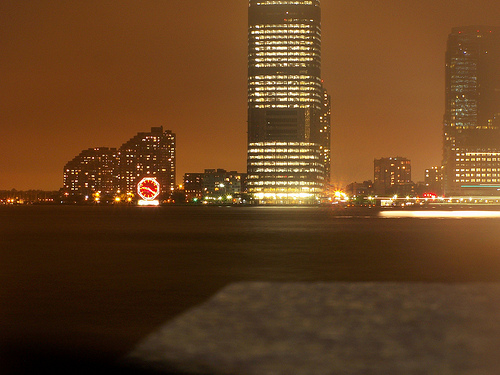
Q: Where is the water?
A: Next to building.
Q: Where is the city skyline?
A: In background.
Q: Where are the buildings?
A: Behind the road.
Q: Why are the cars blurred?
A: Long exposure.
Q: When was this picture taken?
A: Near twilight.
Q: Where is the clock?
A: On the left building.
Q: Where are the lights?
A: On the buildings.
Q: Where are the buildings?
A: In a city.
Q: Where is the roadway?
A: In front of the city.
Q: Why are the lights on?
A: It is night.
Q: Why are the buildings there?
A: Offices.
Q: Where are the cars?
A: On the roads.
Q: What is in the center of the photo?
A: A tall building with lights.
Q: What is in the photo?
A: Building.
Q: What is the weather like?
A: Calm.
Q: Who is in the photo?
A: Nobody.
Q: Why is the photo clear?
A: The area is lit.